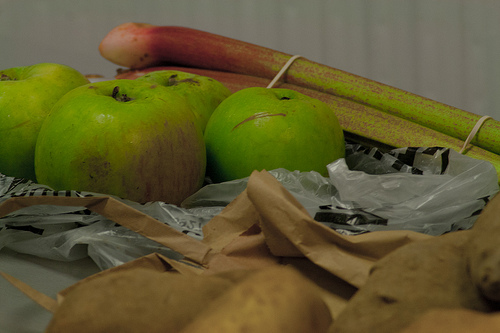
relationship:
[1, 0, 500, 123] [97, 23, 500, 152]
wall behind fruit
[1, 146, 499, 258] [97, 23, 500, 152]
bags are under fruit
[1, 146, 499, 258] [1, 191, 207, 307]
bags has a handle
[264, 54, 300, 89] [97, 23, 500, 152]
rubber band around fruit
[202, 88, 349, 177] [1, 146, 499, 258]
apple sitting on bags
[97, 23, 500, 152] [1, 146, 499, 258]
fruit on top of bags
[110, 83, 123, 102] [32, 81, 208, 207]
stem on top of apple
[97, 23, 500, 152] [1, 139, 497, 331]
fruit on table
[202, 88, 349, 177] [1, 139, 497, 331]
apple on table